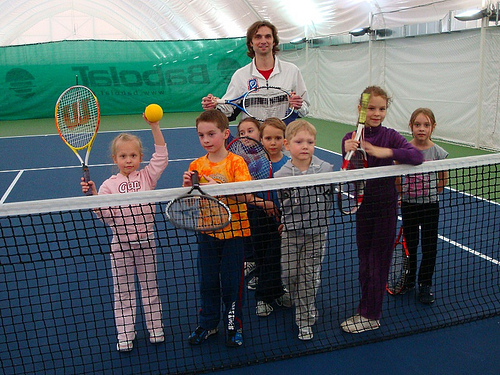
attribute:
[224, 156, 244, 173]
shirt — orange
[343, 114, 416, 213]
track suit — purple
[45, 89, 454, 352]
child — young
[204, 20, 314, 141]
man — tennis lesson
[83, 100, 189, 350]
child — young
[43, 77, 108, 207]
racquet — tennis 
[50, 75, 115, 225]
racquet — tennis 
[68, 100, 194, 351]
child — young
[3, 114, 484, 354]
court — tennis, blue tennis , tennis court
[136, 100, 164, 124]
ball — tennis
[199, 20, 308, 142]
coach — tennis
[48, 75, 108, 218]
racket — tennis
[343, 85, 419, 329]
girl — purple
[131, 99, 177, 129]
ball. — tennis, Yellow kid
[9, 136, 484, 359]
court. — tennis, Blue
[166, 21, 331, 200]
instructor. — Tennis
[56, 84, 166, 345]
girl. — Little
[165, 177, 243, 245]
racket. — red tennis, Orange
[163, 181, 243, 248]
racket. — silver tennis, Black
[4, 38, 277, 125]
tent — Green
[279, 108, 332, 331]
boy — Blonde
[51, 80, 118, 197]
racket —  red tennis , White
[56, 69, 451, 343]
kids — standing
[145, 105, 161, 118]
ball — yellow, tennis ball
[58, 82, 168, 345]
girl — track suit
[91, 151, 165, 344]
suit — pink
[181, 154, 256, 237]
shirt — orange, tie-dyed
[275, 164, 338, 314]
suit — grey, track suit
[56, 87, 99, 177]
racket — orange, yellow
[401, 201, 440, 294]
pants — black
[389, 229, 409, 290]
racket — black, red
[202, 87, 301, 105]
hands — man's hands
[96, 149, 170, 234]
sweater — pink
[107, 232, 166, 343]
pants — pink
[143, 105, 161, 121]
ball — yellow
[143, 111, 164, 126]
hand — girl's hand, left hand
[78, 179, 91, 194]
hand — girl's hand, right hand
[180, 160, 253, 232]
shirt — orange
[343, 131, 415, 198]
shirt — purple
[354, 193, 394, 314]
pants — purple